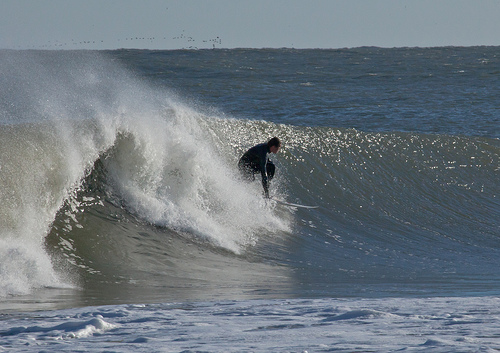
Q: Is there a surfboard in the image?
A: Yes, there is a surfboard.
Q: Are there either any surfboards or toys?
A: Yes, there is a surfboard.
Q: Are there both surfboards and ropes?
A: No, there is a surfboard but no ropes.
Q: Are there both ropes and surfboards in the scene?
A: No, there is a surfboard but no ropes.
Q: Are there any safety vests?
A: No, there are no safety vests.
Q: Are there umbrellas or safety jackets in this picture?
A: No, there are no safety jackets or umbrellas.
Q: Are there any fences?
A: No, there are no fences.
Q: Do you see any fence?
A: No, there are no fences.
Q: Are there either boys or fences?
A: No, there are no fences or boys.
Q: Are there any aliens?
A: No, there are no aliens.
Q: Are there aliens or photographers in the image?
A: No, there are no aliens or photographers.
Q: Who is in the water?
A: The man is in the water.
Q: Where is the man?
A: The man is in the water.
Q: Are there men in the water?
A: Yes, there is a man in the water.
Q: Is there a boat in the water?
A: No, there is a man in the water.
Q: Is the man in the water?
A: Yes, the man is in the water.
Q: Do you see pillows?
A: No, there are no pillows.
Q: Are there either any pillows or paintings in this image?
A: No, there are no pillows or paintings.